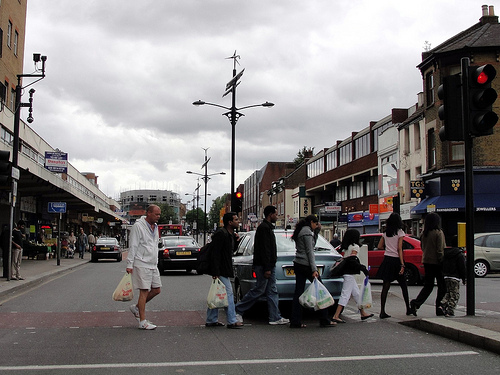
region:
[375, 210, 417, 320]
The woman wearing a pink shirt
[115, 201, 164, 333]
The man wearing a white hoodie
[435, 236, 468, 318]
a small boy wearing camouflage pants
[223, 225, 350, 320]
The blue car behind the people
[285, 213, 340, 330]
The woman wearing a grey sweater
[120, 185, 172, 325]
man carrying white bag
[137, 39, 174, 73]
white clouds in blue sky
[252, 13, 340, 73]
white clouds in blue sky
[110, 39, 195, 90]
white clouds in blue sky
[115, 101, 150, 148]
white clouds in blue sky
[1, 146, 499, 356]
People walking across a city street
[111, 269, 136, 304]
A plastic bag in a man's hand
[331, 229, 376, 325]
A little girl crossing a street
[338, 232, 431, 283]
A red car pulling into traffic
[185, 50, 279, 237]
Lights on a metal pole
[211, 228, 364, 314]
A blue car on a city street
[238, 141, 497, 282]
Row of buildings lining a busy street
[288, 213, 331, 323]
Woman with a ponytail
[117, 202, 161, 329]
man with white bags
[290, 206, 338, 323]
woman with white bags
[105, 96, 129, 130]
white clouds in blue sky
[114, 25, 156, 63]
white clouds in blue sky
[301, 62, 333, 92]
white clouds in blue sky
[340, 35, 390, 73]
white clouds in blue sky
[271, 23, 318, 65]
white clouds in blue sky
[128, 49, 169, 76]
white clouds in blue sky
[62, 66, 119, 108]
white clouds in blue sky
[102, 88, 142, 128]
white clouds in blue sky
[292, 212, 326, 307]
woman carrying white bags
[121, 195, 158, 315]
man carrying white bags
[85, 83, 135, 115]
white clouds in blue sky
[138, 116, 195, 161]
white clouds in blue sky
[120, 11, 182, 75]
white clouds in blue sky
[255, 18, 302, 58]
white clouds in blue sky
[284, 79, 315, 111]
white clouds in blue sky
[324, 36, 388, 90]
white clouds in blue sky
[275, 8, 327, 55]
white clouds in blue sky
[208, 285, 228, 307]
a plastic bag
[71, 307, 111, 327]
a crosswalk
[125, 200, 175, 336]
a man walking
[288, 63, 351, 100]
clouds in the sky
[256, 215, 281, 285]
man wearing a black shirt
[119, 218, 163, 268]
man wearing a white shirt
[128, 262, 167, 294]
man wearing white shorts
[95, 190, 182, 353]
man walking across street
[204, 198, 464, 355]
people walking across street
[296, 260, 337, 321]
lady holding bags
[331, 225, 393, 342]
girl holding bag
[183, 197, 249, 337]
boy holding bag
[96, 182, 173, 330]
man holding bag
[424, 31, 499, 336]
traffic light on street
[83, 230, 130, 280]
car parked on side of road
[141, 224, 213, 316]
car driving on street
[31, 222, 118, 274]
people walking on side walk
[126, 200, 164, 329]
guy is holding plastic bag